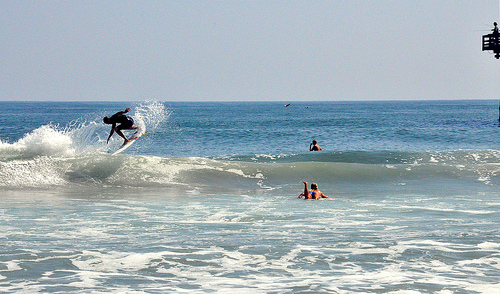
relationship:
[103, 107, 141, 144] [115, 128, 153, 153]
man in motion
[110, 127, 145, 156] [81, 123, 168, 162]
surfboard riding wave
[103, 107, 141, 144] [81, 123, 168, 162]
man riding wave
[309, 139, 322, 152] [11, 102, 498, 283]
man in ocean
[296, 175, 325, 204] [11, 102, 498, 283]
person in ocean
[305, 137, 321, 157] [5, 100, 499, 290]
man in water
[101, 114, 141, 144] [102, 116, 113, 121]
man has head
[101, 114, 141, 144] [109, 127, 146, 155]
man on surfboard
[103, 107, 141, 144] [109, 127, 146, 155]
man on surfboard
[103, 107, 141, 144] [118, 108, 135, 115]
man has arm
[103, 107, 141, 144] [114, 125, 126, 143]
man has leg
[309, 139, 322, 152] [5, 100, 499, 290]
man in water